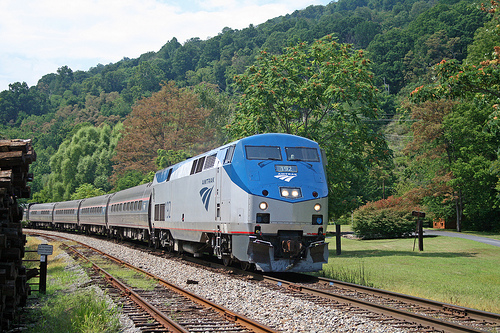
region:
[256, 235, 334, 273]
The engine of a train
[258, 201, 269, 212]
the headlight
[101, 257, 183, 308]
the railway line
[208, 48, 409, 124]
the green trees in background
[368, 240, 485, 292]
the green grass on the right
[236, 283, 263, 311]
concrete stones along the railway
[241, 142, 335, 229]
the head of a train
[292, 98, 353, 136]
tree branches on the side of a train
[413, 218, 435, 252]
trunk of a tree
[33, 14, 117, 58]
white clouds in the sky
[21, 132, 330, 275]
Passenger train on a train track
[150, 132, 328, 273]
Single blue and silver train engine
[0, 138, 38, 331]
A pile of logs beside a train track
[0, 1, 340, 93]
Sky mostly covered by clouds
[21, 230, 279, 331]
An empty section of train tracks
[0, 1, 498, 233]
A hillside covered with trees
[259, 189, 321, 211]
Lights on the front of a train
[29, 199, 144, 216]
Windows on the passenger cars of a train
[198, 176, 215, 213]
Brand and logo on the side of the train engine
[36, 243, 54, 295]
Posted sign beside a train track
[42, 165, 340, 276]
blue and grey train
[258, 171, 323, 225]
white headlights on train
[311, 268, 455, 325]
train on rusty tracks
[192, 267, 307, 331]
grey gravel between tracks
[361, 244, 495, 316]
green field beside tracks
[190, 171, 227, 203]
blue logo on side of train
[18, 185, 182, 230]
grey cars behind engine car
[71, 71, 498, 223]
forest of trees behind train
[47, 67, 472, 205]
tall and green forest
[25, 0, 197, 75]
white puffy clouds in sky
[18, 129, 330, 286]
A blue and silver train.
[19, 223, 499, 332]
A section of train tracks.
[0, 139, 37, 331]
A pile of wood.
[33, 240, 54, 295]
A small sign post.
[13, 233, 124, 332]
An area of grass.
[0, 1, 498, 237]
A background of trees.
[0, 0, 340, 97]
A section of sky.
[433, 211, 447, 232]
A distant orange object.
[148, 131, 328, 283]
A large train engine.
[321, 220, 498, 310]
An area of grass.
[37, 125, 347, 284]
this is a train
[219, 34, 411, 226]
this is a bushy tree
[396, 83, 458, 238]
this is a bushy tree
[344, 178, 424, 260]
this is a bushy tree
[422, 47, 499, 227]
this is a bushy tree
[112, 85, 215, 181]
this is a bushy tree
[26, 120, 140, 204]
this is a bushy tree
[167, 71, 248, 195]
this is a bushy tree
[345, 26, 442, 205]
this is a bushy tree